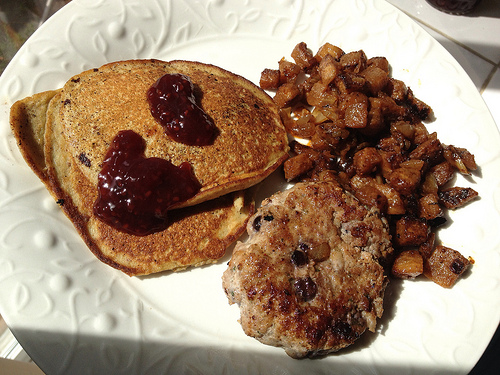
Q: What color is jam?
A: Red.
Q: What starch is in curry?
A: Potato.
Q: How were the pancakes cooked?
A: Fried.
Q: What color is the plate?
A: White.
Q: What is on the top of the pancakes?
A: Fruit preserve.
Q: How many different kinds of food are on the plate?
A: Three.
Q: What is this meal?
A: Breakfast.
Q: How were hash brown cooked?
A: Roasted.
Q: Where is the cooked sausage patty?
A: Next to the hash browns?.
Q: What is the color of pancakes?
A: Golden brown.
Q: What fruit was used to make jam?
A: Strawberry.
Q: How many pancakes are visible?
A: 3.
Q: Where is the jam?
A: On the pancakes.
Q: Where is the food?
A: On the plate.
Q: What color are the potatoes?
A: Brown.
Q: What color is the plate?
A: White.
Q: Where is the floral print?
A: On the plate.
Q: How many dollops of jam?
A: 2.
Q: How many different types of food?
A: 3.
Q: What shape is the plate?
A: Round.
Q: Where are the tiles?
A: On the counter.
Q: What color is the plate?
A: White.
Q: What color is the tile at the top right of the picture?
A: White.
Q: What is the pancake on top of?
A: Other pancake.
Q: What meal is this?
A: Breakfast.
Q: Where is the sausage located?
A: Middle.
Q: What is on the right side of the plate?
A: Potatoes.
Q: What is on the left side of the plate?
A: Pancakes.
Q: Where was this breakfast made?
A: Home.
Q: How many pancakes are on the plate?
A: Three.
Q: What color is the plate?
A: White.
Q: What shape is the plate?
A: Round.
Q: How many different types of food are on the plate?
A: Three.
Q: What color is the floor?
A: White.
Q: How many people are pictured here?
A: Zero.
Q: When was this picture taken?
A: Breakfast.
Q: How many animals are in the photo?
A: Zero.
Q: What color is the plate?
A: White.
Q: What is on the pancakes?
A: Jam.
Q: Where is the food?
A: On the plate.